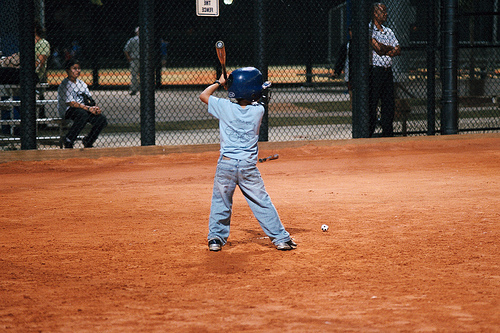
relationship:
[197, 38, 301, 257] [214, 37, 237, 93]
boy holding bat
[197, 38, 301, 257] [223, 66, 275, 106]
boy wearing helmet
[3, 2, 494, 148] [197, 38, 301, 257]
fence behind boy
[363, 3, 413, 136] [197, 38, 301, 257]
man watching boy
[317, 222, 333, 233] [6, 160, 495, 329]
ball on ground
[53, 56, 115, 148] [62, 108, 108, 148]
kid wearing jeans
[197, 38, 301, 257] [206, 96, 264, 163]
boy wearing shirt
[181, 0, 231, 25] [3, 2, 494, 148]
sign on fence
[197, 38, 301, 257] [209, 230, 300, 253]
boy wearing shoes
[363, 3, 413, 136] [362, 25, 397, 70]
man wearing shirt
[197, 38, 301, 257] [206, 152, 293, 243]
boy wearing pants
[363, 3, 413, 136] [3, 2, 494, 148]
man near fence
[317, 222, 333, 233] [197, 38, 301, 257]
ball near boy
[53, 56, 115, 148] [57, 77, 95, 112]
kid wearing shirt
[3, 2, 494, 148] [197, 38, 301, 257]
fence near boy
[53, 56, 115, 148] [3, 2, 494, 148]
kid near fence